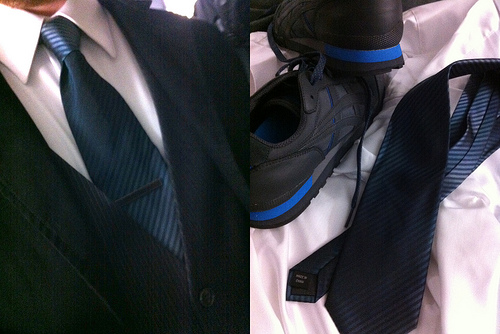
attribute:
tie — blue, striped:
[35, 15, 186, 265]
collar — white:
[1, 1, 117, 83]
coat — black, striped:
[1, 1, 251, 331]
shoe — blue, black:
[266, 1, 405, 78]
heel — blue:
[293, 41, 403, 72]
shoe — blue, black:
[252, 66, 391, 226]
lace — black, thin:
[345, 75, 371, 228]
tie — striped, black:
[286, 58, 499, 333]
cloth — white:
[251, 0, 497, 333]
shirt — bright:
[1, 0, 166, 190]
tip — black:
[289, 270, 317, 298]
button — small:
[197, 287, 216, 309]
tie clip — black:
[114, 180, 161, 209]